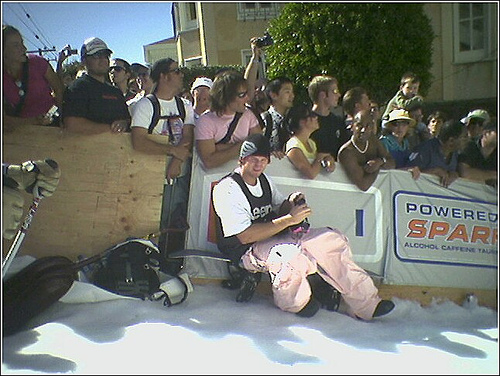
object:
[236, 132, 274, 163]
hat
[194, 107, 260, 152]
pink shirt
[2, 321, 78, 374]
shadow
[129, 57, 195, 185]
people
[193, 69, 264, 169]
people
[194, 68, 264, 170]
man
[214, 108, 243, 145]
strap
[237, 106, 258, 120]
shoulder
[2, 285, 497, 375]
snow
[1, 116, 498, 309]
wall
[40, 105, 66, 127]
camera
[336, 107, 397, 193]
man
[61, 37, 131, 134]
man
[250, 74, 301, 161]
man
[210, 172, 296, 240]
shirt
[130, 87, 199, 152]
shirt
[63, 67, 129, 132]
shirt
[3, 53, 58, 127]
shirt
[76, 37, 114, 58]
hat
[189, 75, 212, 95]
hat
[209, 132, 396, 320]
man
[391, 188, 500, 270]
sign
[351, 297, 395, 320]
shoes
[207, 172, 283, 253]
vest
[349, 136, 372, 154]
white necklace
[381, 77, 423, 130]
boy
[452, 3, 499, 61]
window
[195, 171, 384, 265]
sign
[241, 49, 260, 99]
arm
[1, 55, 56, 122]
woman shirt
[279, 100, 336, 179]
person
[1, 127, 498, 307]
blockade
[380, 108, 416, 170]
woman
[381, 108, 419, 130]
hat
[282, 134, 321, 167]
shirt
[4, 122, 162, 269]
board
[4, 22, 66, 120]
person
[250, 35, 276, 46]
camera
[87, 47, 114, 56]
brim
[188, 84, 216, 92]
brim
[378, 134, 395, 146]
man's shoulders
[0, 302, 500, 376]
ground